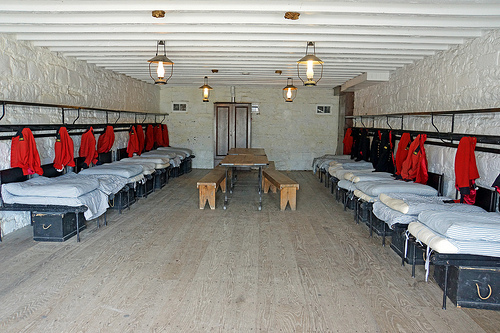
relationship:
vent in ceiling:
[340, 72, 390, 95] [1, 0, 498, 87]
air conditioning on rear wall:
[172, 100, 188, 112] [161, 87, 209, 158]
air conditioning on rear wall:
[313, 103, 333, 115] [262, 88, 342, 165]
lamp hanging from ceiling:
[138, 42, 183, 86] [28, 42, 461, 109]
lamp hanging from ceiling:
[146, 42, 176, 86] [1, 0, 498, 87]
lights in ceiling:
[149, 50, 326, 105] [8, 18, 492, 85]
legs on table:
[192, 185, 218, 210] [214, 127, 278, 181]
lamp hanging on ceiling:
[146, 42, 176, 86] [5, 5, 495, 80]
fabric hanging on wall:
[48, 120, 77, 173] [4, 43, 157, 238]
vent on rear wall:
[314, 103, 334, 115] [161, 87, 342, 170]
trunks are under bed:
[427, 249, 482, 305] [398, 193, 497, 298]